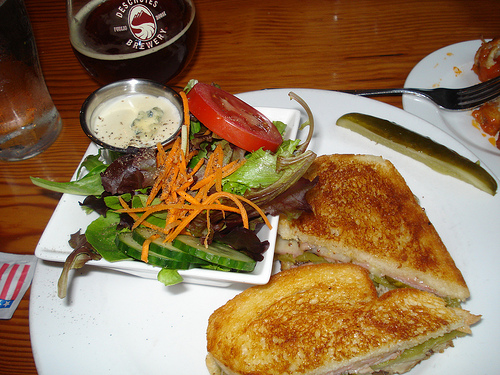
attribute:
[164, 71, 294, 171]
tomato — large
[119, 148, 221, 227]
carrots — thin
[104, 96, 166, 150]
dressing — white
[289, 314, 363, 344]
bread — white, toasted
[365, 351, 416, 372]
meat — white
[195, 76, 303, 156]
slice — tomato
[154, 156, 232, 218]
parts — orange, carrots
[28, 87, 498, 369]
plate — white, round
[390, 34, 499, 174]
plate — smaller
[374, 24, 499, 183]
plate — smaller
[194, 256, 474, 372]
sandwich — half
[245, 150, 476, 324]
sandwich — half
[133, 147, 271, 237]
strips — sliced , carrot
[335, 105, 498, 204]
pickle — slice, green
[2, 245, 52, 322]
packet — red, white, blue, sugar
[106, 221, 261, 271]
slices — three, cucumber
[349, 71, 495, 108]
fork — silver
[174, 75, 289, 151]
tomato — red, slice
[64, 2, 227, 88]
glass — beer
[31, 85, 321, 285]
plate — square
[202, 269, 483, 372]
sandwich — half, grilled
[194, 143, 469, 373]
sandwich — grilled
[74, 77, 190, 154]
cup — silver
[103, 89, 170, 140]
dressing — salad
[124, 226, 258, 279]
slices — three, cucumber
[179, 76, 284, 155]
tomato slice — thick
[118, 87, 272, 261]
carrot — shredded, orange, shaved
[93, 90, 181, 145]
salad dressing — white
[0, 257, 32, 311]
flag — red, white, and blue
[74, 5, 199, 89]
beer — dark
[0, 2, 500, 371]
table — wood